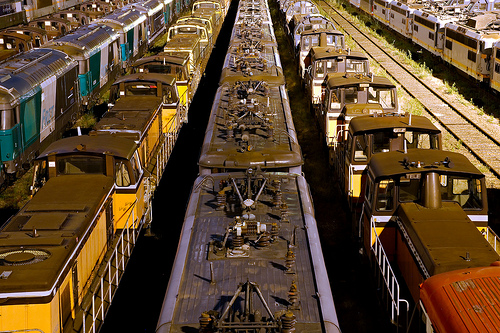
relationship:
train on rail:
[289, 16, 395, 81] [313, 0, 500, 183]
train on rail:
[0, 0, 236, 333] [313, 0, 500, 183]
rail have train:
[313, 0, 500, 183] [0, 0, 236, 333]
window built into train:
[395, 167, 482, 213] [359, 146, 484, 328]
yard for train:
[3, 2, 500, 330] [0, 0, 236, 333]